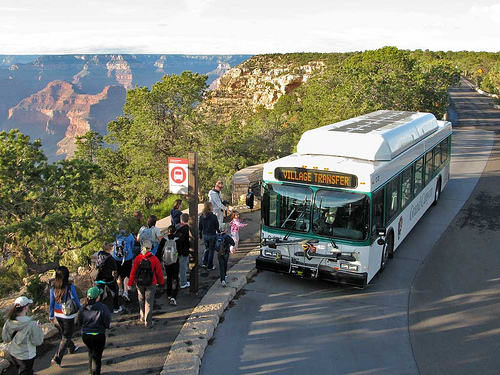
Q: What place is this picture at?
A: It is at the road.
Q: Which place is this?
A: It is a road.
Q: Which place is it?
A: It is a road.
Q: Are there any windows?
A: Yes, there is a window.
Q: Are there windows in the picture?
A: Yes, there is a window.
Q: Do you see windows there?
A: Yes, there is a window.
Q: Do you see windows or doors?
A: Yes, there is a window.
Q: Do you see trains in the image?
A: No, there are no trains.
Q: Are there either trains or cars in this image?
A: No, there are no trains or cars.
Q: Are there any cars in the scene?
A: No, there are no cars.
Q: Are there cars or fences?
A: No, there are no cars or fences.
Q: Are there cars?
A: No, there are no cars.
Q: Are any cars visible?
A: No, there are no cars.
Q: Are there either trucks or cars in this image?
A: No, there are no cars or trucks.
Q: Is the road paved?
A: Yes, the road is paved.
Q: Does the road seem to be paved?
A: Yes, the road is paved.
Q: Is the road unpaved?
A: No, the road is paved.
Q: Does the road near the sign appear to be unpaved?
A: No, the road is paved.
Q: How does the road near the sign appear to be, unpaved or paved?
A: The road is paved.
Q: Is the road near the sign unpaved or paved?
A: The road is paved.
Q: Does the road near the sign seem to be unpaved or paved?
A: The road is paved.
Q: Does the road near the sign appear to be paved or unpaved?
A: The road is paved.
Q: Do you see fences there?
A: No, there are no fences.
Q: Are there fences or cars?
A: No, there are no fences or cars.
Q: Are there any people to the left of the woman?
A: Yes, there are people to the left of the woman.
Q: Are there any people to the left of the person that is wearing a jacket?
A: Yes, there are people to the left of the woman.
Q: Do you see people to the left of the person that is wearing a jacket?
A: Yes, there are people to the left of the woman.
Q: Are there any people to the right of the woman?
A: No, the people are to the left of the woman.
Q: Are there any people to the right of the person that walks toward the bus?
A: No, the people are to the left of the woman.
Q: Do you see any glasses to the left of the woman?
A: No, there are people to the left of the woman.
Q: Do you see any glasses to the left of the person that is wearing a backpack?
A: No, there are people to the left of the woman.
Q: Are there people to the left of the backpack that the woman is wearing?
A: Yes, there are people to the left of the backpack.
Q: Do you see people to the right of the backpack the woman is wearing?
A: No, the people are to the left of the backpack.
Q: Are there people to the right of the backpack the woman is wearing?
A: No, the people are to the left of the backpack.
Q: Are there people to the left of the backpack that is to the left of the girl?
A: Yes, there are people to the left of the backpack.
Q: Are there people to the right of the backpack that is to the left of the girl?
A: No, the people are to the left of the backpack.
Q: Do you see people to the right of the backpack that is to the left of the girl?
A: No, the people are to the left of the backpack.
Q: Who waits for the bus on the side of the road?
A: The people wait for the bus.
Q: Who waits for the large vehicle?
A: The people wait for the bus.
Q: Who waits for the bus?
A: The people wait for the bus.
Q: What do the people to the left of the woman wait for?
A: The people wait for the bus.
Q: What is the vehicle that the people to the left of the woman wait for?
A: The vehicle is a bus.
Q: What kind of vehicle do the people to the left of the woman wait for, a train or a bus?
A: The people wait for a bus.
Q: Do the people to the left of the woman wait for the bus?
A: Yes, the people wait for the bus.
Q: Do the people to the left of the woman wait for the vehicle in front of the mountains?
A: Yes, the people wait for the bus.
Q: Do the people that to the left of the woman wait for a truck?
A: No, the people wait for the bus.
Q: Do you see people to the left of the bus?
A: Yes, there are people to the left of the bus.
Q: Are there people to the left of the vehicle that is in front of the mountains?
A: Yes, there are people to the left of the bus.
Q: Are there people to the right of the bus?
A: No, the people are to the left of the bus.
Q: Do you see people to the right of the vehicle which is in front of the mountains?
A: No, the people are to the left of the bus.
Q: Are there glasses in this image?
A: No, there are no glasses.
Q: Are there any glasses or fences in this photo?
A: No, there are no glasses or fences.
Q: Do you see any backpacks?
A: Yes, there is a backpack.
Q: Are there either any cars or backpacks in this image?
A: Yes, there is a backpack.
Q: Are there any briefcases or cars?
A: No, there are no cars or briefcases.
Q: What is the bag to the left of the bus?
A: The bag is a backpack.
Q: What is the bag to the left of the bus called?
A: The bag is a backpack.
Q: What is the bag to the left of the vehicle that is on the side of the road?
A: The bag is a backpack.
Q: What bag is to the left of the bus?
A: The bag is a backpack.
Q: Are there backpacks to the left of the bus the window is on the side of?
A: Yes, there is a backpack to the left of the bus.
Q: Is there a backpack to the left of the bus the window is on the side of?
A: Yes, there is a backpack to the left of the bus.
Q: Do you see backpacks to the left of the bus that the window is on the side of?
A: Yes, there is a backpack to the left of the bus.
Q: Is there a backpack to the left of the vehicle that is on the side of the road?
A: Yes, there is a backpack to the left of the bus.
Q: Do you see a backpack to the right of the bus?
A: No, the backpack is to the left of the bus.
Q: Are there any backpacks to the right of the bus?
A: No, the backpack is to the left of the bus.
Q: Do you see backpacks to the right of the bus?
A: No, the backpack is to the left of the bus.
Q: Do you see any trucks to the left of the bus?
A: No, there is a backpack to the left of the bus.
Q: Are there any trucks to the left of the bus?
A: No, there is a backpack to the left of the bus.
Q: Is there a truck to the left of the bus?
A: No, there is a backpack to the left of the bus.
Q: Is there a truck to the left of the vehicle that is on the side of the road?
A: No, there is a backpack to the left of the bus.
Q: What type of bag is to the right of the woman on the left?
A: The bag is a backpack.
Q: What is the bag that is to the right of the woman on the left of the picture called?
A: The bag is a backpack.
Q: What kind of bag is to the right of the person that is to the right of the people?
A: The bag is a backpack.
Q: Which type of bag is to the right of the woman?
A: The bag is a backpack.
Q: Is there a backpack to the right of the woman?
A: Yes, there is a backpack to the right of the woman.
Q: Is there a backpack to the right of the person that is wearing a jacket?
A: Yes, there is a backpack to the right of the woman.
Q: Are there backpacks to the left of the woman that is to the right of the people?
A: No, the backpack is to the right of the woman.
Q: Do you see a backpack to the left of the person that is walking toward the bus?
A: No, the backpack is to the right of the woman.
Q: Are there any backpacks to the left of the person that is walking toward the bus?
A: No, the backpack is to the right of the woman.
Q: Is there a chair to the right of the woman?
A: No, there is a backpack to the right of the woman.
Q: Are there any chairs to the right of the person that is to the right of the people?
A: No, there is a backpack to the right of the woman.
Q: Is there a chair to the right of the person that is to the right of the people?
A: No, there is a backpack to the right of the woman.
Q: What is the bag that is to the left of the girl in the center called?
A: The bag is a backpack.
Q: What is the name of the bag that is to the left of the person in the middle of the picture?
A: The bag is a backpack.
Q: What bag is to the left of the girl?
A: The bag is a backpack.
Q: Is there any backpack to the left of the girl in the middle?
A: Yes, there is a backpack to the left of the girl.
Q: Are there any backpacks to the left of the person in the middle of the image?
A: Yes, there is a backpack to the left of the girl.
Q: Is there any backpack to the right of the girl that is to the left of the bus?
A: No, the backpack is to the left of the girl.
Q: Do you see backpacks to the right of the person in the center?
A: No, the backpack is to the left of the girl.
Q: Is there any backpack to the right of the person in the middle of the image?
A: No, the backpack is to the left of the girl.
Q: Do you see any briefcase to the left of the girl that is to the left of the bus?
A: No, there is a backpack to the left of the girl.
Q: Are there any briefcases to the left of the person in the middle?
A: No, there is a backpack to the left of the girl.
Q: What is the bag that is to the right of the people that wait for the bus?
A: The bag is a backpack.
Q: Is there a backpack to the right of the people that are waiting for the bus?
A: Yes, there is a backpack to the right of the people.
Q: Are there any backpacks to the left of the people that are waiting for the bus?
A: No, the backpack is to the right of the people.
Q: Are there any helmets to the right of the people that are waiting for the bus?
A: No, there is a backpack to the right of the people.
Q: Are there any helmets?
A: No, there are no helmets.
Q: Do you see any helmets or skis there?
A: No, there are no helmets or skis.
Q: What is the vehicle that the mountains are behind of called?
A: The vehicle is a bus.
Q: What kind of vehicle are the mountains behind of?
A: The mountains are behind the bus.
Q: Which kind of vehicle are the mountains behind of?
A: The mountains are behind the bus.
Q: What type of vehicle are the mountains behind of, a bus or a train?
A: The mountains are behind a bus.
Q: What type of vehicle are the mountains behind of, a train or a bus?
A: The mountains are behind a bus.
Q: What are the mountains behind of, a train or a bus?
A: The mountains are behind a bus.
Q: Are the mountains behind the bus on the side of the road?
A: Yes, the mountains are behind the bus.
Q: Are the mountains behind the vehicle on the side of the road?
A: Yes, the mountains are behind the bus.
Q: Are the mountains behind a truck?
A: No, the mountains are behind the bus.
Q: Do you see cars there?
A: No, there are no cars.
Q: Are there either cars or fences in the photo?
A: No, there are no cars or fences.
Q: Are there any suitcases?
A: No, there are no suitcases.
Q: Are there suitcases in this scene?
A: No, there are no suitcases.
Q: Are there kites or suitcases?
A: No, there are no suitcases or kites.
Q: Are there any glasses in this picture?
A: No, there are no glasses.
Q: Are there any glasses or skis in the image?
A: No, there are no glasses or skis.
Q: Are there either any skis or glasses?
A: No, there are no glasses or skis.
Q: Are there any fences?
A: No, there are no fences.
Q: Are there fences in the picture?
A: No, there are no fences.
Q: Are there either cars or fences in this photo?
A: No, there are no fences or cars.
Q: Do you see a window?
A: Yes, there is a window.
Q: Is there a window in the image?
A: Yes, there is a window.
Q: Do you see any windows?
A: Yes, there is a window.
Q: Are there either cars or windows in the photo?
A: Yes, there is a window.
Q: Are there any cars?
A: No, there are no cars.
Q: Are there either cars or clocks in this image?
A: No, there are no cars or clocks.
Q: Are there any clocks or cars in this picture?
A: No, there are no cars or clocks.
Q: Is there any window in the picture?
A: Yes, there is a window.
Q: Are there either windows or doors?
A: Yes, there is a window.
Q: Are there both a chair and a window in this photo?
A: No, there is a window but no chairs.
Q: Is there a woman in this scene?
A: Yes, there is a woman.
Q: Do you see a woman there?
A: Yes, there is a woman.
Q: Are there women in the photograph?
A: Yes, there is a woman.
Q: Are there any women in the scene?
A: Yes, there is a woman.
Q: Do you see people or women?
A: Yes, there is a woman.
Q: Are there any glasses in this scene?
A: No, there are no glasses.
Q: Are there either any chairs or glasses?
A: No, there are no glasses or chairs.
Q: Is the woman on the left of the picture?
A: Yes, the woman is on the left of the image.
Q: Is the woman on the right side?
A: No, the woman is on the left of the image.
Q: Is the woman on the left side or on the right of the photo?
A: The woman is on the left of the image.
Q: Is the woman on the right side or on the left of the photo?
A: The woman is on the left of the image.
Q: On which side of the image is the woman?
A: The woman is on the left of the image.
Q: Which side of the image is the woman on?
A: The woman is on the left of the image.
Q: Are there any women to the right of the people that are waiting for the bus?
A: Yes, there is a woman to the right of the people.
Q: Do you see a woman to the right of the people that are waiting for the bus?
A: Yes, there is a woman to the right of the people.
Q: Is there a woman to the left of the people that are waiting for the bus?
A: No, the woman is to the right of the people.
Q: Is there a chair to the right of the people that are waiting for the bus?
A: No, there is a woman to the right of the people.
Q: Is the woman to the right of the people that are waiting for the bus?
A: Yes, the woman is to the right of the people.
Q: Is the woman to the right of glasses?
A: No, the woman is to the right of the people.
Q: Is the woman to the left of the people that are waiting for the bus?
A: No, the woman is to the right of the people.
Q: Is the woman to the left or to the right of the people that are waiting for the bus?
A: The woman is to the right of the people.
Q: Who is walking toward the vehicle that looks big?
A: The woman is walking toward the bus.